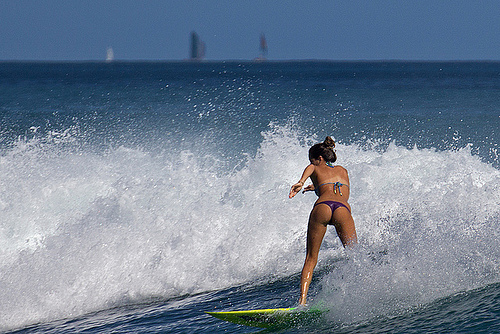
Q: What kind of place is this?
A: It is an ocean.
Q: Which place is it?
A: It is an ocean.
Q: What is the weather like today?
A: It is clear.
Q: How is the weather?
A: It is clear.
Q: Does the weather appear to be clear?
A: Yes, it is clear.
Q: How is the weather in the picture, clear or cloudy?
A: It is clear.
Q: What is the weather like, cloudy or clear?
A: It is clear.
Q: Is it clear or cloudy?
A: It is clear.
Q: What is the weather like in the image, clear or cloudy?
A: It is clear.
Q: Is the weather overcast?
A: No, it is clear.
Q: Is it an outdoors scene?
A: Yes, it is outdoors.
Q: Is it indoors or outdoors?
A: It is outdoors.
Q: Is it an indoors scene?
A: No, it is outdoors.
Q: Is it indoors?
A: No, it is outdoors.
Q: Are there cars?
A: No, there are no cars.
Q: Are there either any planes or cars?
A: No, there are no cars or planes.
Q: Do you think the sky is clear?
A: Yes, the sky is clear.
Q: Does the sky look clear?
A: Yes, the sky is clear.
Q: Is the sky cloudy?
A: No, the sky is clear.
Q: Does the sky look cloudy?
A: No, the sky is clear.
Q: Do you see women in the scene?
A: Yes, there is a woman.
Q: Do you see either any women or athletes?
A: Yes, there is a woman.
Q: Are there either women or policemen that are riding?
A: Yes, the woman is riding.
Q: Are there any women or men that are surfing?
A: Yes, the woman is surfing.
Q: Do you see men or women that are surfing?
A: Yes, the woman is surfing.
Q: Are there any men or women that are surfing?
A: Yes, the woman is surfing.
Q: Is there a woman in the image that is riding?
A: Yes, there is a woman that is riding.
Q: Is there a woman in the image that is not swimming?
A: Yes, there is a woman that is riding.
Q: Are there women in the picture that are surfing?
A: Yes, there is a woman that is surfing.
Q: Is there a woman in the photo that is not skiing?
A: Yes, there is a woman that is surfing.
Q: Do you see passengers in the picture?
A: No, there are no passengers.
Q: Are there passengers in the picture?
A: No, there are no passengers.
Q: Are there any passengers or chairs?
A: No, there are no passengers or chairs.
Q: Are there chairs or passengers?
A: No, there are no passengers or chairs.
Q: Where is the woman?
A: The woman is in the ocean.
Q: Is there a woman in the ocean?
A: Yes, there is a woman in the ocean.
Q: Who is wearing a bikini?
A: The woman is wearing a bikini.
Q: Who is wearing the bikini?
A: The woman is wearing a bikini.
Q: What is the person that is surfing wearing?
A: The woman is wearing a bikini.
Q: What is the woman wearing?
A: The woman is wearing a bikini.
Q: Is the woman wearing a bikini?
A: Yes, the woman is wearing a bikini.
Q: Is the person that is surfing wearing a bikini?
A: Yes, the woman is wearing a bikini.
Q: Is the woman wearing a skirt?
A: No, the woman is wearing a bikini.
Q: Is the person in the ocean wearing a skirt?
A: No, the woman is wearing a bikini.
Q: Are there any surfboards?
A: Yes, there is a surfboard.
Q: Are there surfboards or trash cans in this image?
A: Yes, there is a surfboard.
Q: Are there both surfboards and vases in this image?
A: No, there is a surfboard but no vases.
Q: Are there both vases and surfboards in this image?
A: No, there is a surfboard but no vases.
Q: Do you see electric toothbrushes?
A: No, there are no electric toothbrushes.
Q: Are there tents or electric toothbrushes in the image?
A: No, there are no electric toothbrushes or tents.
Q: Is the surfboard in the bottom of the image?
A: Yes, the surfboard is in the bottom of the image.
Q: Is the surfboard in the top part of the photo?
A: No, the surfboard is in the bottom of the image.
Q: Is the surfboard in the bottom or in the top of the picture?
A: The surfboard is in the bottom of the image.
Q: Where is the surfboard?
A: The surfboard is in the ocean.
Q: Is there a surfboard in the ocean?
A: Yes, there is a surfboard in the ocean.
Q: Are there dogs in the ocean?
A: No, there is a surfboard in the ocean.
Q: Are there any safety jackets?
A: No, there are no safety jackets.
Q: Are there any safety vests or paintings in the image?
A: No, there are no safety vests or paintings.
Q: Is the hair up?
A: Yes, the hair is up.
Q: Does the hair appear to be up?
A: Yes, the hair is up.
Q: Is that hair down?
A: No, the hair is up.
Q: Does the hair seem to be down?
A: No, the hair is up.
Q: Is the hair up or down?
A: The hair is up.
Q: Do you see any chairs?
A: No, there are no chairs.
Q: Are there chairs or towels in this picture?
A: No, there are no chairs or towels.